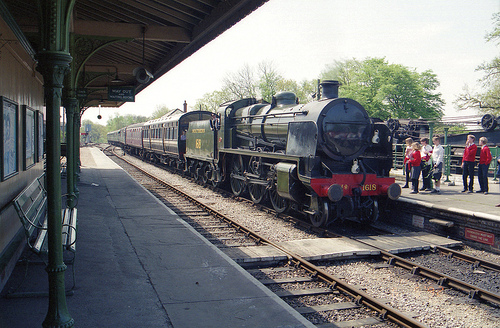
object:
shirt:
[462, 142, 478, 162]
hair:
[411, 142, 422, 150]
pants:
[462, 160, 476, 191]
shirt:
[432, 144, 445, 166]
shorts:
[430, 162, 442, 183]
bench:
[9, 176, 79, 298]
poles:
[32, 1, 73, 328]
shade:
[0, 168, 340, 327]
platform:
[1, 146, 318, 327]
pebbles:
[329, 263, 420, 297]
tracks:
[95, 146, 423, 328]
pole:
[65, 32, 76, 208]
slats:
[295, 301, 362, 314]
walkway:
[217, 230, 463, 268]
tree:
[309, 54, 447, 124]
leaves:
[370, 82, 392, 89]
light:
[132, 66, 154, 85]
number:
[362, 183, 376, 191]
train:
[106, 78, 402, 229]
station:
[0, 0, 500, 327]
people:
[406, 141, 421, 194]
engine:
[228, 79, 402, 229]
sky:
[41, 0, 500, 127]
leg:
[71, 264, 77, 295]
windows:
[164, 121, 179, 139]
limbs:
[453, 94, 500, 112]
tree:
[452, 10, 500, 118]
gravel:
[248, 210, 275, 232]